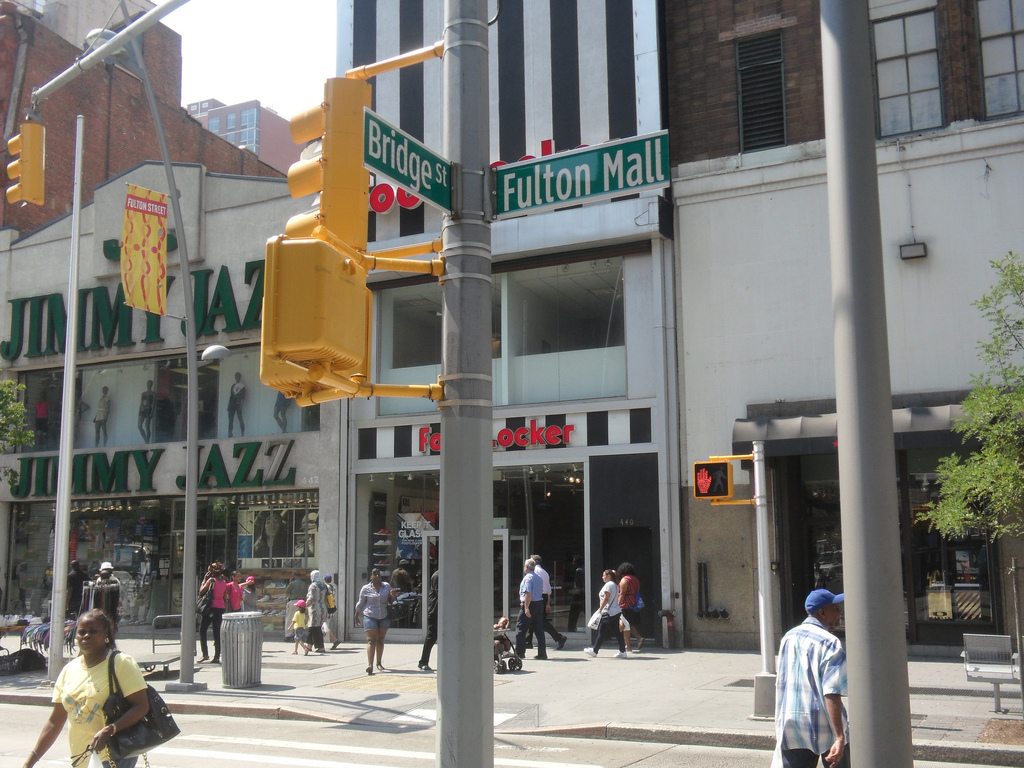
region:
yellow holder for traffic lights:
[211, 31, 467, 425]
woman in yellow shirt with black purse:
[14, 599, 185, 767]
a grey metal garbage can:
[209, 606, 280, 693]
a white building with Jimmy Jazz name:
[7, 150, 361, 670]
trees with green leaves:
[909, 242, 1023, 619]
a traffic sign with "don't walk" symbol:
[688, 437, 786, 687]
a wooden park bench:
[952, 627, 1023, 723]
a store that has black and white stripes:
[317, 1, 688, 663]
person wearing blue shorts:
[346, 561, 401, 689]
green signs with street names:
[361, 104, 674, 213]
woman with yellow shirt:
[20, 609, 182, 765]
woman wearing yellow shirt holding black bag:
[20, 613, 194, 765]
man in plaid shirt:
[771, 581, 845, 765]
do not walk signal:
[688, 458, 761, 507]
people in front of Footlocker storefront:
[334, 2, 692, 680]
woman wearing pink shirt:
[187, 559, 235, 667]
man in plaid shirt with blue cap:
[774, 587, 864, 765]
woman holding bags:
[579, 561, 634, 661]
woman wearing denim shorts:
[351, 565, 403, 679]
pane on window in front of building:
[874, 91, 914, 140]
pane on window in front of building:
[900, 12, 942, 61]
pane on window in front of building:
[876, 54, 910, 99]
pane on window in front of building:
[904, 50, 936, 95]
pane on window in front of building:
[905, 87, 945, 136]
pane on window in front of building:
[980, 68, 1020, 121]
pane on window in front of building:
[979, 32, 1017, 75]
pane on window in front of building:
[975, 2, 1013, 37]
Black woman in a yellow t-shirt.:
[22, 608, 152, 767]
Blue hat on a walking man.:
[801, 586, 849, 612]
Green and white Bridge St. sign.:
[362, 107, 457, 212]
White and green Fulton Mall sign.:
[492, 129, 673, 222]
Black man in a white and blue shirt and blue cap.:
[776, 587, 853, 766]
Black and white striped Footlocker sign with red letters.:
[356, 406, 654, 460]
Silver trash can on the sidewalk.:
[218, 610, 264, 687]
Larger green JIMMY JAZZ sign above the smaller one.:
[3, 258, 263, 361]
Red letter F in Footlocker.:
[417, 422, 434, 454]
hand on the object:
[594, 423, 804, 578]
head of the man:
[781, 565, 873, 646]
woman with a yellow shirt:
[5, 521, 212, 753]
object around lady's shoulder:
[69, 641, 196, 766]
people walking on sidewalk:
[91, 511, 673, 727]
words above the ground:
[384, 399, 610, 501]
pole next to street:
[708, 411, 803, 652]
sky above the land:
[211, 16, 323, 70]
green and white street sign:
[498, 89, 676, 242]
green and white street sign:
[346, 113, 477, 221]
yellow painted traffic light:
[247, 26, 488, 457]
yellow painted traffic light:
[5, 97, 63, 221]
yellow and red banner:
[109, 181, 182, 330]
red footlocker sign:
[393, 408, 599, 469]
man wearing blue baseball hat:
[740, 572, 867, 766]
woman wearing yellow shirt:
[20, 598, 180, 760]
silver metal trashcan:
[212, 600, 274, 698]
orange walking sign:
[684, 451, 732, 512]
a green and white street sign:
[478, 132, 676, 215]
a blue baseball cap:
[801, 584, 850, 614]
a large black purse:
[108, 653, 172, 726]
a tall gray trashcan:
[220, 612, 262, 686]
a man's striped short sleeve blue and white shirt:
[770, 608, 851, 733]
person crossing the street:
[20, 605, 186, 757]